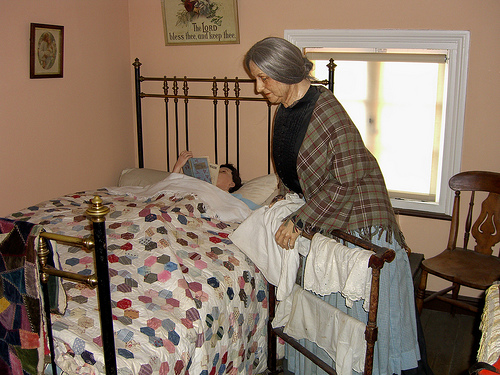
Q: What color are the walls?
A: Pink.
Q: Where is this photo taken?
A: Bedroom.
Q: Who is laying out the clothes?
A: Old lady.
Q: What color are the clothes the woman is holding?
A: White.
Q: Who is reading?
A: Boy.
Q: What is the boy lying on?
A: Bed.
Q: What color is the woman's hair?
A: Grey.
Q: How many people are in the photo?
A: Two.